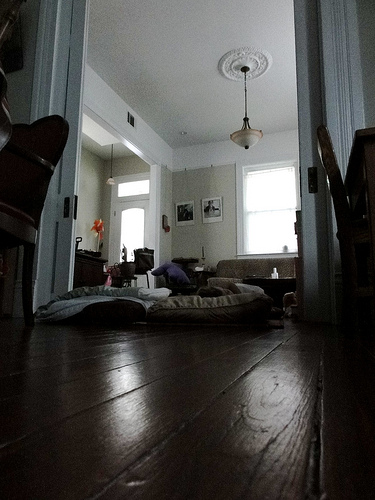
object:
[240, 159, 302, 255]
window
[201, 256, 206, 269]
candle stick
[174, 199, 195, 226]
art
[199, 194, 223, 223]
art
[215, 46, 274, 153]
light fixture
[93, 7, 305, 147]
roof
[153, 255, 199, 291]
chair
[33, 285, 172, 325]
pillow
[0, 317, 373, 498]
floor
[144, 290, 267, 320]
pillow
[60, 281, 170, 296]
pillow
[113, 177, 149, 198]
window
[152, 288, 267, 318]
cushion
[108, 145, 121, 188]
hanging light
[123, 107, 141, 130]
air vent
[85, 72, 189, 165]
pillar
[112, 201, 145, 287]
door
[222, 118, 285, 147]
ceiling light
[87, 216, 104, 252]
flower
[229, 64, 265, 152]
lamp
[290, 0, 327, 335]
door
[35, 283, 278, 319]
pillows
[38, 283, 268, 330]
dog bed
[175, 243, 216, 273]
holder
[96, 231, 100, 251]
stand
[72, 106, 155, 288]
door frame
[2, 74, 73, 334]
chair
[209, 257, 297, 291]
sofa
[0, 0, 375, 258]
wall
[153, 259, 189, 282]
pillow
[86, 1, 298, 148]
ceiling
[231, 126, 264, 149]
shade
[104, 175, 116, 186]
light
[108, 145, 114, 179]
chain